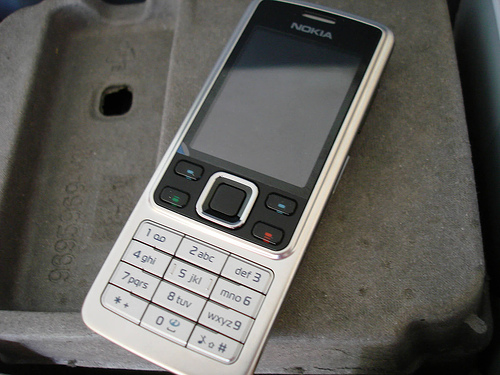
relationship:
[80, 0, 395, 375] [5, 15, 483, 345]
cell phone atop object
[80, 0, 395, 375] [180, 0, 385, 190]
cell phone has screen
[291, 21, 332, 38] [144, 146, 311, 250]
logo has buttons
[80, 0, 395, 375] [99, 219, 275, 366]
cell phone has keypad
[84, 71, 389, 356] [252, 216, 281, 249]
cell phone has button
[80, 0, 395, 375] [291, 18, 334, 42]
cell phone has logo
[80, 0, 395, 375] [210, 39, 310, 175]
cell phone has screen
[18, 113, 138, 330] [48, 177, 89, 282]
object has number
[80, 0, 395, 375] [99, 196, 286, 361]
cell phone has keypad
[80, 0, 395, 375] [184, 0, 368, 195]
cell phone has display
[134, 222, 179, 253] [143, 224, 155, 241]
button has number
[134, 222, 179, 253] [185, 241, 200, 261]
button has number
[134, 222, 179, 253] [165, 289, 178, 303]
button has number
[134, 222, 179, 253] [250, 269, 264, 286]
button has number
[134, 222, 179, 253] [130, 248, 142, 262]
button has number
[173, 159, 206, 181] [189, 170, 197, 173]
button has blue line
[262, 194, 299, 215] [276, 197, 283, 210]
button has blue line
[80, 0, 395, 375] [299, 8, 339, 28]
cell phone has speaker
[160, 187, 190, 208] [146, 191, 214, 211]
button has line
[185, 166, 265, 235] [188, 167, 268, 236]
button has outline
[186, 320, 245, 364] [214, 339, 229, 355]
pound button has pound symbol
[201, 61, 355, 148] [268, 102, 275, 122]
screen seen part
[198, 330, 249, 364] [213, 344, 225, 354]
button has part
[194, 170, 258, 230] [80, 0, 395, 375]
button on cell phone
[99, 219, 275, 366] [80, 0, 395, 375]
keypad on cell phone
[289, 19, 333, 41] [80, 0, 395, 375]
logo on cell phone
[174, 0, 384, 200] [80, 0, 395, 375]
screen on cell phone